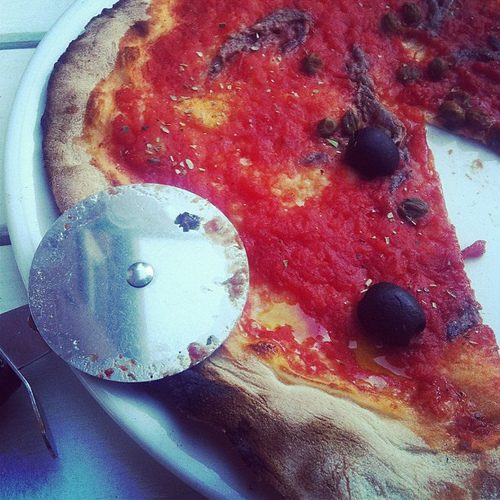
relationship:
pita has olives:
[35, 23, 491, 479] [324, 110, 384, 377]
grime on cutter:
[172, 212, 239, 257] [13, 161, 272, 408]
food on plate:
[38, 3, 498, 496] [106, 396, 237, 498]